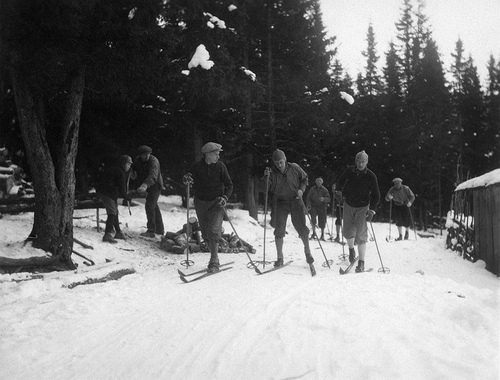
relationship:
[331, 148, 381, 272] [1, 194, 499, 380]
person skiing in snow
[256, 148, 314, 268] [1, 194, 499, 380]
person skiing in snow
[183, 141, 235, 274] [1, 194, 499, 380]
person skiing in snow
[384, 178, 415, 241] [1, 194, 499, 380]
person skiing in snow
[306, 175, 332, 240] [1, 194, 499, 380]
person skiing in snow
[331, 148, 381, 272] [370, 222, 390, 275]
person holding ski pole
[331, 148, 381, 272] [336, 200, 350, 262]
person holding ski pole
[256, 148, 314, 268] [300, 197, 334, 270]
person holding ski pole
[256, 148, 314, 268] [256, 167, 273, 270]
person holding ski pole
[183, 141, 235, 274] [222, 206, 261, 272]
person holding ski pole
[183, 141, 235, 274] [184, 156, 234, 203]
person wearing sweater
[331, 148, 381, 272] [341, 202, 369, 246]
person wearing shorts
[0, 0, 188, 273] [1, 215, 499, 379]
tree on path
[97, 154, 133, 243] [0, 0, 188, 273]
person close to tree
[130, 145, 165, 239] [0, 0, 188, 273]
person close to tree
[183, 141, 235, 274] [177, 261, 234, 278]
person on ski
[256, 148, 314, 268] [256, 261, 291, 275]
person on ski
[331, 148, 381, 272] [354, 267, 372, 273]
person on ski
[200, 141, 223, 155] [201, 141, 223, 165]
hat on person's head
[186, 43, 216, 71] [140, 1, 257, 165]
snow on tree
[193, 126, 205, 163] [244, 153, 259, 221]
tree trunk next to tree trunk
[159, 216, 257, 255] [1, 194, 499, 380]
pile on snow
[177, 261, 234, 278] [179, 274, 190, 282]
ski has tip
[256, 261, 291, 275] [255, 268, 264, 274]
ski has tip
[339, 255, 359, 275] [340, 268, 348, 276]
ski has tip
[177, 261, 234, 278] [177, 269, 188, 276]
ski has tip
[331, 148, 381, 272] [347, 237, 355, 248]
person wearing sock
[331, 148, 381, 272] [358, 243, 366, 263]
person wearing sock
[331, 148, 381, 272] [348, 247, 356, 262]
person wearing ski boot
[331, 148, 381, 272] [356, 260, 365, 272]
person wearing ski boot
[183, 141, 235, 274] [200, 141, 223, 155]
person wearing hat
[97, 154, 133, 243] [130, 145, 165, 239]
person helps person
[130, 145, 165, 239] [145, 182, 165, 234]
person has pants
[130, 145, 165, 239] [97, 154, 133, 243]
person helps person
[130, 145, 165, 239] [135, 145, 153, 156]
person wears cap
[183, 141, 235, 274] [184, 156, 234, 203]
person wears sweater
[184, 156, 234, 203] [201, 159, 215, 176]
sweater over shirt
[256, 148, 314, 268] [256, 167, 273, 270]
person has ski pole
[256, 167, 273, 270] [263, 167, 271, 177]
ski pole in hand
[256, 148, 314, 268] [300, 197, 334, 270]
person has ski pole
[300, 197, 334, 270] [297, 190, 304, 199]
ski pole in hand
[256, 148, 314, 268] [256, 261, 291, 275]
person wearing ski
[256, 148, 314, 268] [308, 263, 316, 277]
person wearing ski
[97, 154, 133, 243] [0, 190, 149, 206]
person sawing wood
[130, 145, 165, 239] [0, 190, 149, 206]
person sawing wood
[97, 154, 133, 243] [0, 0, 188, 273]
person stands to right of tree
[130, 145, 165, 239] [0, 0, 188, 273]
person stands to right of tree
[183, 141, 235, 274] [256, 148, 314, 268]
person looking to person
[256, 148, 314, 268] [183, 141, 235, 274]
person right of person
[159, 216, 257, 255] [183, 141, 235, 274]
pile behind person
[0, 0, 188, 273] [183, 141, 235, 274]
tree left of person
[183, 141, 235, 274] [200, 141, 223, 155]
person wears hat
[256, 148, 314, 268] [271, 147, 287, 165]
person wears hat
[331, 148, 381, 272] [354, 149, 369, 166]
person wears hat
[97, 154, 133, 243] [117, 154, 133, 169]
person wears hat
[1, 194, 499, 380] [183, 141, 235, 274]
snow under person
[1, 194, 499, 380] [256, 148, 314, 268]
snow under person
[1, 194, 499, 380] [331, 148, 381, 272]
snow under person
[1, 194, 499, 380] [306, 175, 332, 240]
snow under person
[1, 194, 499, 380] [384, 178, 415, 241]
snow under person